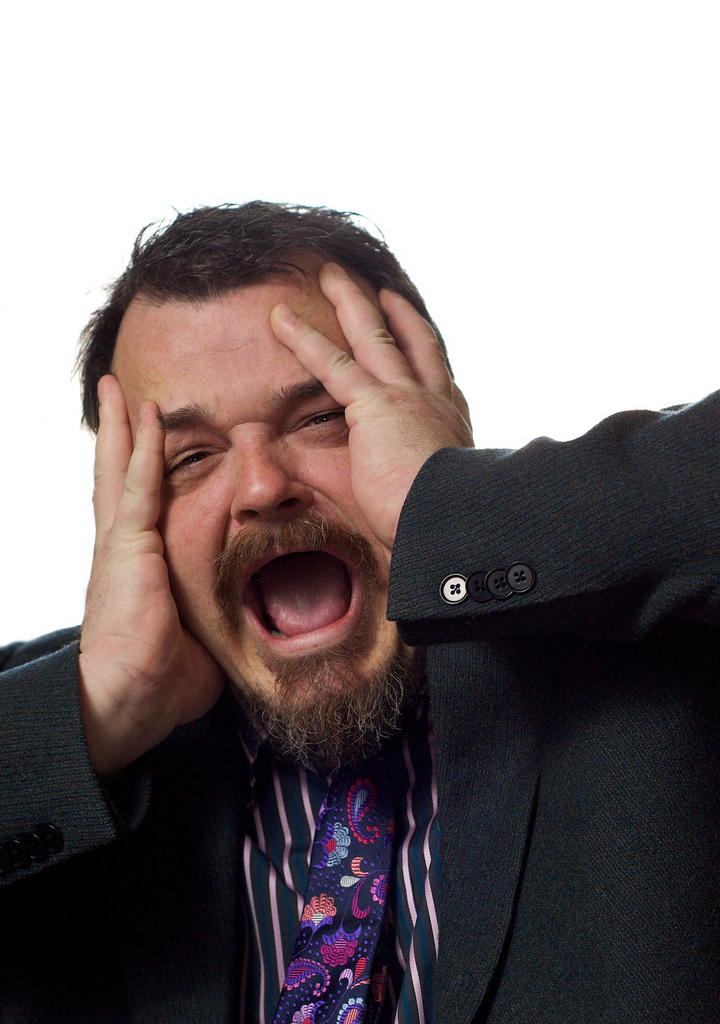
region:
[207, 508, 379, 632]
the mustache is brown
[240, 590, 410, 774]
the chin hair is brown and medium length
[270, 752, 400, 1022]
the tie is multi-colored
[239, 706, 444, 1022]
the button up shirt is striped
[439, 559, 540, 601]
the buttons are black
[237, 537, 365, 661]
the mouth is opened very wide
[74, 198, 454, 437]
the hair is short and brown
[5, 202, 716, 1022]
the man holding his hands to his face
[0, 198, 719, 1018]
the man has his mouth opened very wide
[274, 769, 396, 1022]
the tie has multiple colors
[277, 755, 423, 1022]
paisley tie on the man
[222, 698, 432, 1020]
striped shirt on the man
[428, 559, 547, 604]
four buttons on his suit sleeve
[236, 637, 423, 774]
beard on the man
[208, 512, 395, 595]
mustache on the man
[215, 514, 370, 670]
the man's open mouth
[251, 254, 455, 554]
guy's left hand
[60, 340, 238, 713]
guys right hand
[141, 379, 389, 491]
guys eyes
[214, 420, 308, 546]
guys nose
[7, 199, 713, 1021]
man with his mouth open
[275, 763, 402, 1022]
blue tie with floral design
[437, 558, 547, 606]
buttons on a blazer jacket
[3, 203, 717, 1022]
man with a mustache and beard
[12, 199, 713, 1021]
man wearing a blazer jacket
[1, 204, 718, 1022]
man wearing a striped shirt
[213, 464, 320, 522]
nose of a adult male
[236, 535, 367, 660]
mouth of a adult male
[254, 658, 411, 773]
beard of a adult male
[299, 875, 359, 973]
a view of design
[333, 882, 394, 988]
a design in tie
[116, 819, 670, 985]
suit wearing by man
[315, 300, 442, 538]
hand of the person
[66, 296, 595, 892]
face of the person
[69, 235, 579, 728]
man in shock pose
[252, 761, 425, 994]
Me with a different color tie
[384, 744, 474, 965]
A man with a blue and white striped shirt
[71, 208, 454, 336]
A man with brown hair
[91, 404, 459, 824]
A name with his mouth open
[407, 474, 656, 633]
Four buttons on a jacket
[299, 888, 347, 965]
A flower on the tie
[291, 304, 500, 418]
A man with no ring on his hand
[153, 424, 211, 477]
eye on a man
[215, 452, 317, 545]
nose on the man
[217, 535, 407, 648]
a mouth on the man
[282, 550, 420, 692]
a tounge on the man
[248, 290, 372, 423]
a finger on the hand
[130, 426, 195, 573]
a finger on the hand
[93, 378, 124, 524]
a finger on the hand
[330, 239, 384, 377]
a finger on the hand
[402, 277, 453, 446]
a finger on the hand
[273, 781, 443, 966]
a tie on the man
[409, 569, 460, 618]
a button on the jacket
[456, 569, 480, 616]
a button on the jacket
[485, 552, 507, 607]
a button on the jacket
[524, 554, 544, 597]
a button on the jacket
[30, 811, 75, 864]
a button on the jacket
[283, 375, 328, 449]
eye on the face